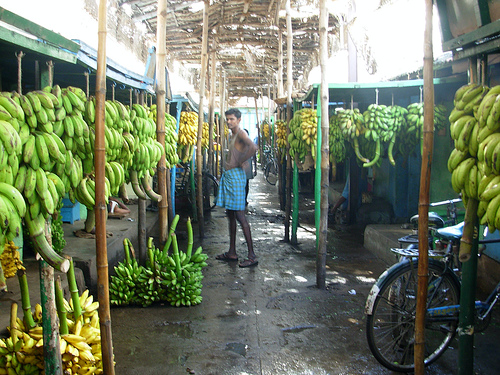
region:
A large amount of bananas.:
[1, 43, 498, 374]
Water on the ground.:
[150, 312, 263, 366]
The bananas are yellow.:
[2, 295, 113, 372]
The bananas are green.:
[110, 244, 208, 309]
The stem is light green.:
[19, 220, 86, 282]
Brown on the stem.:
[29, 253, 76, 275]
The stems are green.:
[155, 211, 205, 271]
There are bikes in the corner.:
[371, 182, 496, 372]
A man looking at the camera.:
[216, 105, 268, 277]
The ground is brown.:
[196, 265, 379, 370]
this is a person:
[201, 92, 288, 256]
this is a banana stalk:
[361, 85, 391, 193]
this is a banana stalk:
[385, 96, 445, 171]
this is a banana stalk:
[281, 71, 335, 188]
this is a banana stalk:
[155, 216, 210, 310]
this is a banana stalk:
[102, 251, 136, 312]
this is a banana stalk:
[10, 69, 87, 284]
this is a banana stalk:
[50, 81, 121, 233]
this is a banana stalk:
[118, 76, 149, 210]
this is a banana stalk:
[172, 95, 210, 193]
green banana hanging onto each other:
[25, 95, 53, 129]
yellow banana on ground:
[70, 322, 103, 374]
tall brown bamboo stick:
[90, 50, 119, 371]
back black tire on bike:
[369, 259, 458, 374]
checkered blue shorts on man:
[217, 167, 250, 212]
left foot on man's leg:
[240, 256, 263, 268]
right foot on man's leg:
[216, 245, 235, 264]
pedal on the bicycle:
[481, 297, 499, 326]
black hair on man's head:
[226, 106, 245, 117]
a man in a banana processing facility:
[124, 79, 264, 276]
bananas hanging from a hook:
[361, 95, 385, 145]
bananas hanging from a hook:
[333, 94, 360, 140]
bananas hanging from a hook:
[5, 85, 55, 222]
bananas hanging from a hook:
[44, 84, 87, 201]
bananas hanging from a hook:
[108, 98, 129, 194]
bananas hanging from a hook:
[128, 101, 143, 173]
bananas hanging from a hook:
[443, 86, 483, 217]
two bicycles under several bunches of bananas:
[352, 153, 497, 368]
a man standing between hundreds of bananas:
[116, 90, 398, 290]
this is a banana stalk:
[131, 249, 168, 308]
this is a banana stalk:
[55, 251, 118, 371]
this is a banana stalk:
[4, 300, 43, 371]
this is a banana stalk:
[447, 68, 478, 257]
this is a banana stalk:
[461, 70, 496, 256]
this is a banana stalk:
[404, 80, 427, 167]